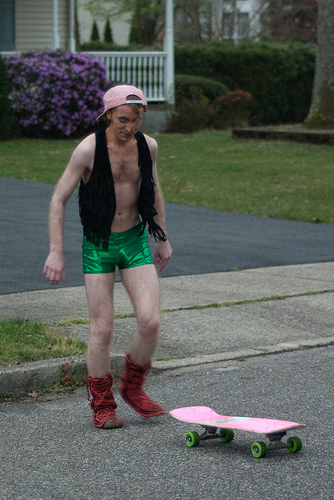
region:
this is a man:
[79, 93, 190, 418]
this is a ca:
[109, 83, 121, 95]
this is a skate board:
[188, 408, 283, 456]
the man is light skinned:
[119, 150, 140, 206]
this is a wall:
[15, 0, 71, 38]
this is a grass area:
[7, 321, 38, 352]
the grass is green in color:
[6, 322, 20, 345]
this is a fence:
[224, 45, 297, 103]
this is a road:
[196, 205, 237, 262]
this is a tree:
[315, 8, 327, 142]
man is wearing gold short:
[72, 198, 214, 321]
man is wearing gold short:
[44, 83, 225, 452]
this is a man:
[40, 83, 165, 443]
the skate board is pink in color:
[255, 417, 276, 429]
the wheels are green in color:
[250, 434, 305, 460]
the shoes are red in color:
[90, 367, 152, 429]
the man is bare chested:
[117, 158, 137, 203]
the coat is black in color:
[83, 183, 112, 233]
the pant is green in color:
[107, 237, 142, 261]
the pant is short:
[113, 234, 140, 268]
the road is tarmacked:
[98, 442, 168, 495]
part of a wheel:
[244, 436, 266, 473]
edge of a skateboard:
[209, 416, 235, 445]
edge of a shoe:
[99, 410, 125, 427]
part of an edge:
[28, 382, 53, 400]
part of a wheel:
[196, 426, 216, 439]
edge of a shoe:
[86, 372, 105, 385]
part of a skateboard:
[219, 412, 259, 480]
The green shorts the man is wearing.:
[81, 229, 157, 268]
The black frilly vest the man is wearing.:
[83, 125, 165, 250]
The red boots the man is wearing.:
[75, 363, 169, 429]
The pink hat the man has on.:
[93, 86, 149, 118]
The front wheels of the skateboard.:
[250, 436, 302, 462]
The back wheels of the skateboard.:
[183, 429, 238, 445]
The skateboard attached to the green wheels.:
[170, 392, 309, 436]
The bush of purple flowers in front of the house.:
[10, 43, 106, 129]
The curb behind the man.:
[0, 362, 125, 388]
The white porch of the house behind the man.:
[56, 40, 186, 103]